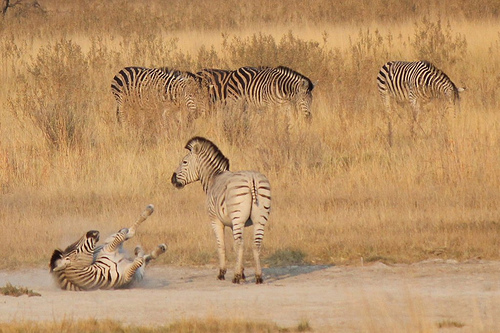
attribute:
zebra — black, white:
[179, 142, 285, 269]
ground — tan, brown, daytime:
[8, 11, 472, 231]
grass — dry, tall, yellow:
[299, 128, 462, 199]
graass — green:
[321, 149, 372, 172]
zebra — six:
[39, 54, 457, 285]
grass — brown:
[147, 12, 409, 40]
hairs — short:
[275, 60, 308, 79]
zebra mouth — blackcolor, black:
[162, 173, 186, 189]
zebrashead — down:
[450, 87, 479, 119]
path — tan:
[307, 267, 463, 295]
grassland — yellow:
[350, 169, 474, 219]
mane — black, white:
[426, 62, 449, 78]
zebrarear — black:
[372, 55, 393, 95]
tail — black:
[252, 190, 263, 205]